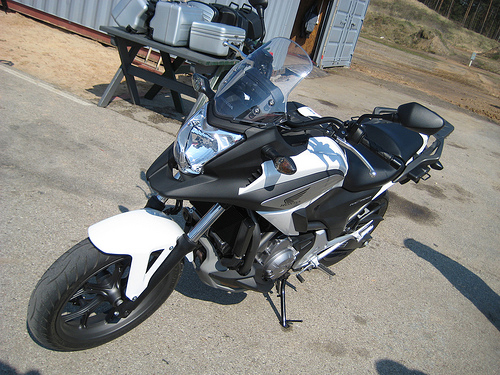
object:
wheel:
[26, 236, 185, 351]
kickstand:
[278, 270, 293, 328]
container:
[110, 0, 154, 38]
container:
[148, 0, 201, 50]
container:
[188, 20, 247, 59]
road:
[1, 63, 500, 373]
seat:
[330, 120, 423, 192]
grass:
[360, 1, 499, 75]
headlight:
[174, 104, 243, 176]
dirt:
[1, 9, 170, 99]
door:
[262, 0, 299, 66]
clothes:
[299, 2, 319, 37]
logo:
[281, 185, 311, 208]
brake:
[223, 41, 251, 65]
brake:
[331, 135, 376, 177]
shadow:
[401, 236, 498, 333]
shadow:
[368, 353, 429, 373]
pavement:
[6, 41, 497, 369]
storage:
[0, 0, 368, 67]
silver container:
[108, 1, 152, 34]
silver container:
[150, 0, 192, 46]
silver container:
[185, 18, 249, 58]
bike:
[25, 36, 455, 351]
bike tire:
[27, 236, 191, 354]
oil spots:
[319, 325, 375, 359]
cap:
[86, 205, 186, 302]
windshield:
[213, 34, 313, 126]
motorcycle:
[24, 36, 456, 354]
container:
[312, 8, 367, 72]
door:
[318, 2, 370, 69]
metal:
[20, 0, 372, 75]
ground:
[1, 0, 499, 373]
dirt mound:
[358, 0, 499, 113]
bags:
[115, 0, 264, 55]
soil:
[0, 10, 123, 94]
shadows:
[1, 200, 498, 373]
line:
[0, 57, 91, 110]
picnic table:
[94, 23, 237, 119]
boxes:
[102, 0, 247, 59]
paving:
[1, 60, 497, 372]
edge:
[0, 62, 177, 139]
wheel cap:
[99, 278, 126, 312]